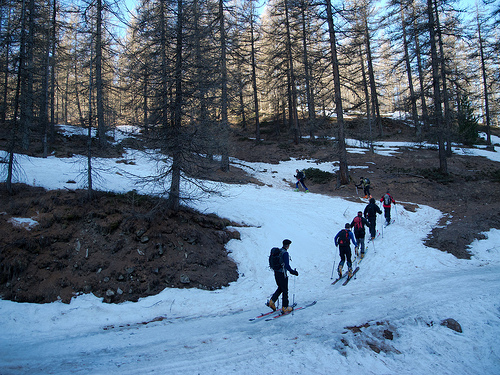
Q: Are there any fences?
A: No, there are no fences.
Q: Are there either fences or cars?
A: No, there are no fences or cars.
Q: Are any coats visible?
A: Yes, there is a coat.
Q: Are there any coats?
A: Yes, there is a coat.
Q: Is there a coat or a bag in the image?
A: Yes, there is a coat.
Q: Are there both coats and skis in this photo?
A: Yes, there are both a coat and skis.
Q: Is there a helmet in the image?
A: No, there are no helmets.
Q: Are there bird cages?
A: No, there are no bird cages.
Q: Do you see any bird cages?
A: No, there are no bird cages.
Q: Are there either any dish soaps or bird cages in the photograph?
A: No, there are no bird cages or dish soaps.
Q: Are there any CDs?
A: No, there are no cds.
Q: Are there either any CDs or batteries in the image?
A: No, there are no CDs or batteries.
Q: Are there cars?
A: No, there are no cars.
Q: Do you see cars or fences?
A: No, there are no cars or fences.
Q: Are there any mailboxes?
A: No, there are no mailboxes.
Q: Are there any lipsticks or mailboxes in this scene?
A: No, there are no mailboxes or lipsticks.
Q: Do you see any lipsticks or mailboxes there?
A: No, there are no mailboxes or lipsticks.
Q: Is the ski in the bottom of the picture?
A: Yes, the ski is in the bottom of the image.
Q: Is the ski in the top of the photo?
A: No, the ski is in the bottom of the image.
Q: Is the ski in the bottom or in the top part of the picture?
A: The ski is in the bottom of the image.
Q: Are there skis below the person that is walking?
A: Yes, there is a ski below the person.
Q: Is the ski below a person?
A: Yes, the ski is below a person.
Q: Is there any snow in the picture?
A: Yes, there is snow.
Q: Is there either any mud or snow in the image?
A: Yes, there is snow.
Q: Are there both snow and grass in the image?
A: No, there is snow but no grass.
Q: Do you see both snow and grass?
A: No, there is snow but no grass.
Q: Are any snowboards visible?
A: No, there are no snowboards.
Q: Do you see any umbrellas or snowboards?
A: No, there are no snowboards or umbrellas.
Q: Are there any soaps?
A: No, there are no soaps.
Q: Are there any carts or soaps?
A: No, there are no soaps or carts.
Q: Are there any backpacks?
A: Yes, there is a backpack.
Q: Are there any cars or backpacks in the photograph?
A: Yes, there is a backpack.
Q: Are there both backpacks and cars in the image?
A: No, there is a backpack but no cars.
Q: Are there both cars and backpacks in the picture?
A: No, there is a backpack but no cars.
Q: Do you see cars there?
A: No, there are no cars.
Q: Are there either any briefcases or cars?
A: No, there are no cars or briefcases.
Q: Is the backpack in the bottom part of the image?
A: Yes, the backpack is in the bottom of the image.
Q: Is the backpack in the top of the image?
A: No, the backpack is in the bottom of the image.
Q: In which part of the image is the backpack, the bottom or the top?
A: The backpack is in the bottom of the image.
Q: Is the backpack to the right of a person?
A: No, the backpack is to the left of a person.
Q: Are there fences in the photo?
A: No, there are no fences.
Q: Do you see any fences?
A: No, there are no fences.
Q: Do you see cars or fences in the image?
A: No, there are no fences or cars.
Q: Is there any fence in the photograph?
A: No, there are no fences.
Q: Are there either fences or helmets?
A: No, there are no fences or helmets.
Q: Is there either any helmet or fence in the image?
A: No, there are no fences or helmets.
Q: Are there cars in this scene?
A: No, there are no cars.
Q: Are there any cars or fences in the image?
A: No, there are no cars or fences.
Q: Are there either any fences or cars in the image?
A: No, there are no cars or fences.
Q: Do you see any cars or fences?
A: No, there are no cars or fences.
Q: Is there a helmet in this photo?
A: No, there are no helmets.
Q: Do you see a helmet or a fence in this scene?
A: No, there are no helmets or fences.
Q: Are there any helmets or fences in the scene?
A: No, there are no helmets or fences.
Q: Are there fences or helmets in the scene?
A: No, there are no helmets or fences.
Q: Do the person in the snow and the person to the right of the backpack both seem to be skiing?
A: Yes, both the person and the person are skiing.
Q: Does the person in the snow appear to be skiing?
A: Yes, the person is skiing.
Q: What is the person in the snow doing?
A: The person is skiing.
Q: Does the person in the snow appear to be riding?
A: No, the person is skiing.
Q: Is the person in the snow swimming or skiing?
A: The person is skiing.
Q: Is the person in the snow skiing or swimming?
A: The person is skiing.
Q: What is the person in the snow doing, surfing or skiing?
A: The person is skiing.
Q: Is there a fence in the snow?
A: No, there is a person in the snow.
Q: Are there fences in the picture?
A: No, there are no fences.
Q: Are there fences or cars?
A: No, there are no fences or cars.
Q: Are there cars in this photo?
A: No, there are no cars.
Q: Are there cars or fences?
A: No, there are no cars or fences.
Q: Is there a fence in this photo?
A: No, there are no fences.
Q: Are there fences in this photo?
A: No, there are no fences.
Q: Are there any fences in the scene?
A: No, there are no fences.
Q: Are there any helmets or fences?
A: No, there are no fences or helmets.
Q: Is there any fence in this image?
A: No, there are no fences.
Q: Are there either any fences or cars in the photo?
A: No, there are no fences or cars.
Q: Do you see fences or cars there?
A: No, there are no fences or cars.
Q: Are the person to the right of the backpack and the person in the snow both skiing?
A: Yes, both the person and the person are skiing.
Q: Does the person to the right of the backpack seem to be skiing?
A: Yes, the person is skiing.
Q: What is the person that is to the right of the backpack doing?
A: The person is skiing.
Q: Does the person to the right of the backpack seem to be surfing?
A: No, the person is skiing.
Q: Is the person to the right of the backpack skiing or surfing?
A: The person is skiing.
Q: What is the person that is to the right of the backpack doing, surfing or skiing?
A: The person is skiing.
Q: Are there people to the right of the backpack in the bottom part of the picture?
A: Yes, there is a person to the right of the backpack.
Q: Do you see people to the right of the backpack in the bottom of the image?
A: Yes, there is a person to the right of the backpack.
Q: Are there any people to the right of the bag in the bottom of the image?
A: Yes, there is a person to the right of the backpack.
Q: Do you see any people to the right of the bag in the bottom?
A: Yes, there is a person to the right of the backpack.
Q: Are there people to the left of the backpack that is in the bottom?
A: No, the person is to the right of the backpack.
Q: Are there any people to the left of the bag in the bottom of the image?
A: No, the person is to the right of the backpack.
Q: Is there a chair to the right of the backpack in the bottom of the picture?
A: No, there is a person to the right of the backpack.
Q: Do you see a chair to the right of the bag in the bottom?
A: No, there is a person to the right of the backpack.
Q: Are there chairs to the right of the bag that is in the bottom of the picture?
A: No, there is a person to the right of the backpack.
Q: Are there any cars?
A: No, there are no cars.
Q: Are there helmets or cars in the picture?
A: No, there are no cars or helmets.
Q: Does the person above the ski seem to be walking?
A: Yes, the person is walking.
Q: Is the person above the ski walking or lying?
A: The person is walking.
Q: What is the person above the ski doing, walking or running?
A: The person is walking.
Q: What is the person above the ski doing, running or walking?
A: The person is walking.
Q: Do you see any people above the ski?
A: Yes, there is a person above the ski.